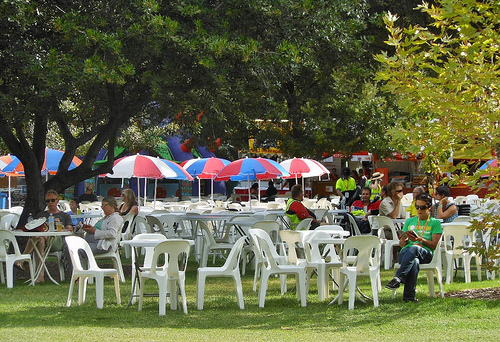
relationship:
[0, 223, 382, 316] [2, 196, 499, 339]
chairs on lawn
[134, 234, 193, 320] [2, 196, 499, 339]
chairs on lawn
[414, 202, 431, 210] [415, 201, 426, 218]
sunglasses on face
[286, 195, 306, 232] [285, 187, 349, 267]
vest on man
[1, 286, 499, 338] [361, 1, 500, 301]
shadows from tree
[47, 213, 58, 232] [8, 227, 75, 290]
bottle on table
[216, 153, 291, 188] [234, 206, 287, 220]
umbrellas above table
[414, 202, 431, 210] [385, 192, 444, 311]
sunglasses on man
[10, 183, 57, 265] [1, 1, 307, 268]
trunk of tree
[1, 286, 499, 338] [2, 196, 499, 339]
shadows on lawn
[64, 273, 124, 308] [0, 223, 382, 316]
legs of chairs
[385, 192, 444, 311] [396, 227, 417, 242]
man has object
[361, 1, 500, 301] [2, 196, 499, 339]
tree above lawn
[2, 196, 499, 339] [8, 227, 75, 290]
lawn beneath table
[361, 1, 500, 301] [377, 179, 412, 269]
tree over people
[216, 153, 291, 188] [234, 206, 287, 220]
umbrellas attached to table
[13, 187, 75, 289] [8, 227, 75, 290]
man at table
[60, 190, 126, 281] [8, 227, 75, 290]
woman at table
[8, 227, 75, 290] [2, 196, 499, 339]
table on lawn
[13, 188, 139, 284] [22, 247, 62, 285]
people sitting in chair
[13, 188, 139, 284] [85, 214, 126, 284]
people sitting in chair